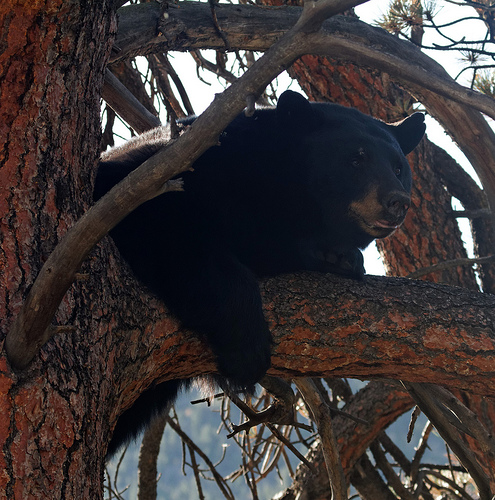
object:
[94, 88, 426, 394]
animal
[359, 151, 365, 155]
mark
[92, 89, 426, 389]
bear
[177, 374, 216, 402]
fur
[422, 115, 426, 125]
tear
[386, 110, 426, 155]
ear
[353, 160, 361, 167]
eye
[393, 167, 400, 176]
eye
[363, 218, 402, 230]
mouth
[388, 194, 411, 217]
nostrils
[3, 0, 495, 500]
day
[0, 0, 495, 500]
tree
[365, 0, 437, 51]
pine needles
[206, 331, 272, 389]
paw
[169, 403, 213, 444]
white clouds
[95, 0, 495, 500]
branches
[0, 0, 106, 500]
sticks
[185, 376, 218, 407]
light